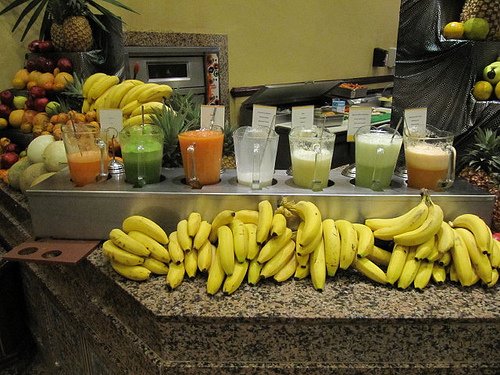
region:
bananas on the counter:
[98, 205, 485, 313]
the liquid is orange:
[58, 116, 127, 186]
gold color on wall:
[273, 29, 359, 53]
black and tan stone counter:
[198, 296, 330, 346]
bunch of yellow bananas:
[152, 207, 386, 276]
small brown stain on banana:
[345, 242, 357, 260]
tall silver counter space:
[57, 182, 156, 214]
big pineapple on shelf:
[45, 3, 107, 54]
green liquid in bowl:
[126, 128, 165, 168]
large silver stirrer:
[249, 109, 282, 153]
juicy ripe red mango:
[23, 65, 64, 85]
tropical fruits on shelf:
[21, 55, 173, 173]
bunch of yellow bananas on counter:
[104, 212, 495, 299]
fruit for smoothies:
[13, 11, 179, 187]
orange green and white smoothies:
[61, 120, 496, 215]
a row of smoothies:
[54, 116, 497, 186]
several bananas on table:
[135, 221, 492, 268]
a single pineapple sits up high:
[40, 1, 121, 50]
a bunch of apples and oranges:
[17, 36, 66, 98]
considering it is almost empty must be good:
[236, 116, 278, 199]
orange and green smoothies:
[51, 110, 239, 187]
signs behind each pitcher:
[85, 102, 440, 145]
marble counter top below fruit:
[111, 278, 454, 344]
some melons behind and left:
[9, 125, 59, 200]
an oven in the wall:
[123, 24, 238, 108]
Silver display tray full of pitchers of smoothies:
[25, 113, 496, 239]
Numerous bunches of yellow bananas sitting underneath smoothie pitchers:
[105, 195, 498, 291]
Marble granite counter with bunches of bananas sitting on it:
[25, 275, 499, 373]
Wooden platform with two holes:
[5, 234, 96, 265]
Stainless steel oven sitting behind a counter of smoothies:
[125, 45, 207, 97]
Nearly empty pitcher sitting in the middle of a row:
[231, 125, 278, 190]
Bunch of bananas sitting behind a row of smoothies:
[85, 68, 174, 128]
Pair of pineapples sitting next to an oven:
[42, 2, 96, 57]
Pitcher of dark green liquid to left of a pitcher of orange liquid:
[118, 122, 165, 182]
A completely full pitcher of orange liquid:
[174, 122, 226, 185]